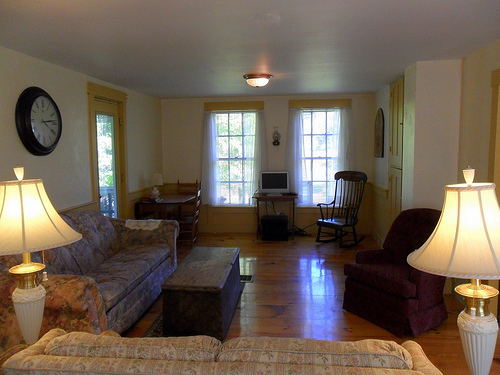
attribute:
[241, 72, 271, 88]
light — domed, ceiling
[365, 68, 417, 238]
door — yellow 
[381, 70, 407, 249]
door — yellow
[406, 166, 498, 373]
lamp — white, gold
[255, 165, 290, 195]
monitor — computer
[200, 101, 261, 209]
window — large, living room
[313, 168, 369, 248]
rocking chair — wooden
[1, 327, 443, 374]
couches —  tan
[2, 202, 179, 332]
couches —  tan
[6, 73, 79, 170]
wall clock — brown, wooden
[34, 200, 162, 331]
couch — cushioned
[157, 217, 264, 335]
table — wooden, living room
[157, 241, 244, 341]
coffee table — wooden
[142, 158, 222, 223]
chairs — wooden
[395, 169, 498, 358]
lamp — identical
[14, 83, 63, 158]
clock — Black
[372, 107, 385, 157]
wall art — a piece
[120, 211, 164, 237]
cloth — White